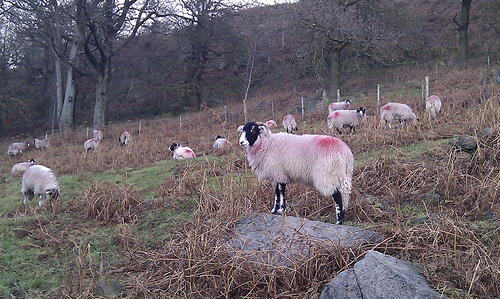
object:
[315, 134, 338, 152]
marking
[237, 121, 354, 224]
sheep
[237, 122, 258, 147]
face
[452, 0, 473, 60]
trees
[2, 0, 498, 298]
hill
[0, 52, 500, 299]
grass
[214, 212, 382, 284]
rock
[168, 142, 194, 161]
sheep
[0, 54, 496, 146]
fence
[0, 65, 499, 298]
field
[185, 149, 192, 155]
paint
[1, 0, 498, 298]
background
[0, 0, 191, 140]
tree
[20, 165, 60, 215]
sheep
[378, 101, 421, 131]
sheep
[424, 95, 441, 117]
sheep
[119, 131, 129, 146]
sheep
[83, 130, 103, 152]
sheep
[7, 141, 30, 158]
sheep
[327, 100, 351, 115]
sheep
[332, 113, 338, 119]
spot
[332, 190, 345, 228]
legs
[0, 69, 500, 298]
straw